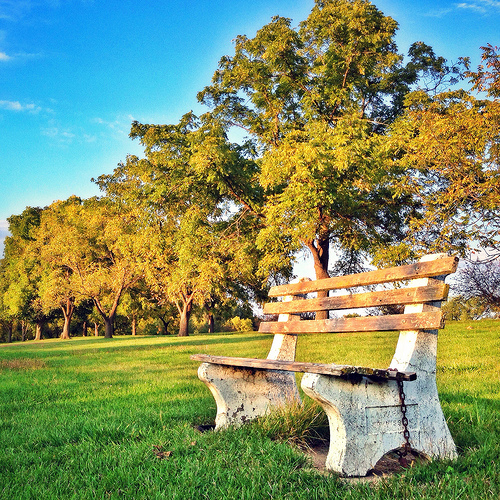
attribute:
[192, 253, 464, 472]
bench — old, wood, concrete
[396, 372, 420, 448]
chain — rusted, metal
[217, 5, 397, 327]
tree — green, large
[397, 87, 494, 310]
tree — green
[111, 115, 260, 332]
tree — green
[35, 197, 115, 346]
tree — green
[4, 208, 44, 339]
tree — green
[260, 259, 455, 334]
top — wood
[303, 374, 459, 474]
legs — concrete, cement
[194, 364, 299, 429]
legs — concrete, cement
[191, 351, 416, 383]
seat — wood, brown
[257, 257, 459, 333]
back — wooden, wood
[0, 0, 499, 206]
sky — blue, bright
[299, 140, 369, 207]
leaves — colorful